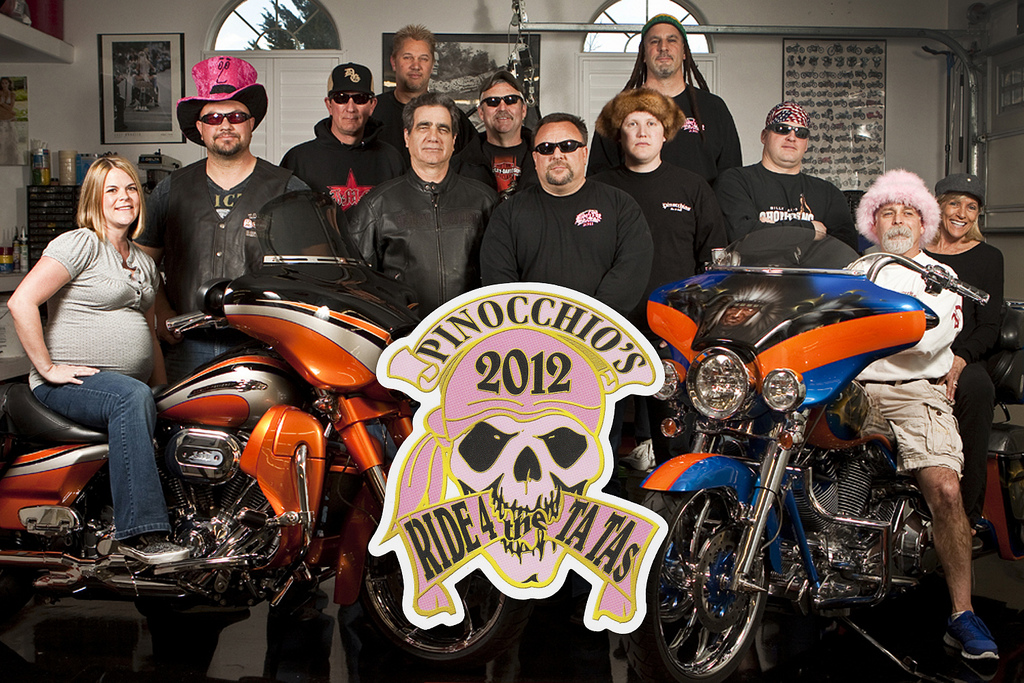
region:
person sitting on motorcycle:
[2, 154, 188, 563]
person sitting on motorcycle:
[835, 166, 1003, 661]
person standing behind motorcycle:
[133, 49, 355, 384]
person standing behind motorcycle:
[282, 62, 403, 239]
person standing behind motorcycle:
[349, 87, 511, 339]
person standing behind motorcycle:
[356, 24, 500, 192]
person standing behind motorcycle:
[471, 71, 540, 201]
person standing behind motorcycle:
[473, 109, 662, 320]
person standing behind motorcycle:
[601, 82, 731, 352]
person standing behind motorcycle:
[588, 10, 750, 275]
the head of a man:
[512, 105, 595, 192]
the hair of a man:
[542, 104, 587, 133]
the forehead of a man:
[531, 124, 580, 140]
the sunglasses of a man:
[529, 134, 588, 160]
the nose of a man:
[539, 145, 579, 162]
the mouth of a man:
[546, 159, 579, 172]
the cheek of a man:
[558, 149, 587, 169]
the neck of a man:
[543, 175, 582, 198]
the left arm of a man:
[591, 197, 664, 311]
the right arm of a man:
[463, 194, 540, 286]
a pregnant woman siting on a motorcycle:
[11, 146, 171, 583]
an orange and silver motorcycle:
[0, 267, 503, 664]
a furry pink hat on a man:
[855, 169, 941, 245]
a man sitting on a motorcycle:
[830, 167, 1005, 668]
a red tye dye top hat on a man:
[177, 52, 267, 148]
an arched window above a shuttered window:
[213, 0, 341, 48]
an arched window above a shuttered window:
[578, 4, 718, 56]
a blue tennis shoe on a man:
[938, 605, 997, 660]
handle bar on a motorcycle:
[864, 245, 988, 306]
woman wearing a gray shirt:
[5, 149, 199, 567]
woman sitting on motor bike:
[0, 147, 523, 657]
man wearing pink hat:
[131, 51, 338, 388]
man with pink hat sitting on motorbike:
[615, 163, 1008, 672]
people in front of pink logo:
[4, 10, 1017, 672]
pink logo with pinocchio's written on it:
[359, 275, 673, 642]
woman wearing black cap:
[911, 166, 1022, 569]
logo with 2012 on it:
[364, 273, 679, 650]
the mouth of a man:
[523, 154, 607, 224]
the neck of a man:
[479, 130, 663, 247]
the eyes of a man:
[392, 98, 479, 156]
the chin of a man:
[394, 139, 470, 235]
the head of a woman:
[67, 139, 160, 267]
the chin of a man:
[70, 124, 263, 261]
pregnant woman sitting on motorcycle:
[11, 149, 230, 567]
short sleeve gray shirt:
[35, 214, 178, 376]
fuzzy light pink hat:
[842, 162, 942, 242]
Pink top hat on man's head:
[169, 51, 268, 138]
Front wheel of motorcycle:
[619, 449, 788, 675]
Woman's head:
[74, 153, 148, 240]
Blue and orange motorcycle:
[640, 241, 1021, 679]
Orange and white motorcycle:
[2, 257, 524, 666]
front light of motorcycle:
[681, 341, 752, 424]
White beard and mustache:
[875, 215, 923, 258]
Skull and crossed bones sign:
[336, 251, 692, 659]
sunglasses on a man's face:
[518, 133, 591, 160]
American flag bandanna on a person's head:
[763, 98, 811, 128]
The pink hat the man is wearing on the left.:
[181, 51, 268, 128]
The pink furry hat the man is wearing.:
[856, 164, 939, 240]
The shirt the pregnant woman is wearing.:
[53, 231, 156, 375]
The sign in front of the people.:
[377, 284, 663, 633]